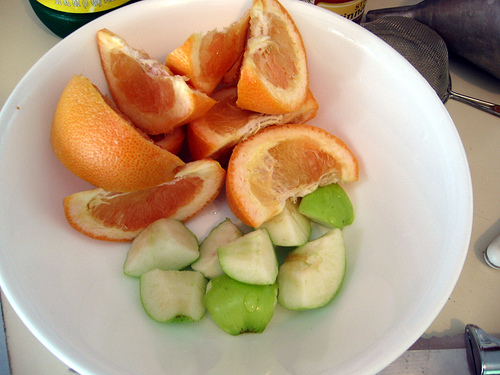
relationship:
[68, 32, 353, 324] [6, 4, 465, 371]
fruit on plate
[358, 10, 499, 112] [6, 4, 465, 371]
strainer near plate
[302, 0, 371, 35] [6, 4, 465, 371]
bottle near plate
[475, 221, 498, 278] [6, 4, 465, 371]
handle near plate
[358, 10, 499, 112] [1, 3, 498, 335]
strainer on counter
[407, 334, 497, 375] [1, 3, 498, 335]
knife on counter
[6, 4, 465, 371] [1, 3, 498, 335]
plate on counter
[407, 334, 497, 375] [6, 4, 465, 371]
knife by plate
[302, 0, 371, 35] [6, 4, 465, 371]
bottle by plate